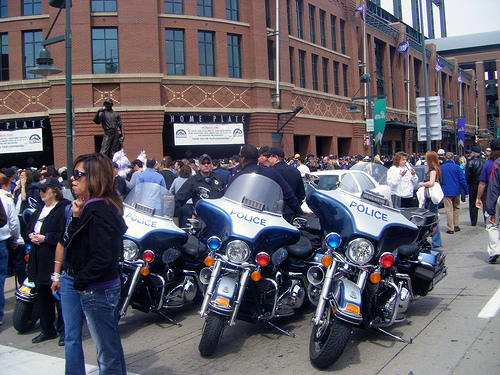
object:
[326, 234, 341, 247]
light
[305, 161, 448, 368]
motorcycle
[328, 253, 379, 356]
light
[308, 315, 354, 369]
tire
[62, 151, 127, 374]
woman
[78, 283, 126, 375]
jeans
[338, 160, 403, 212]
windshield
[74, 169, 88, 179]
glasses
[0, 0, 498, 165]
wall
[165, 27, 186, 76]
window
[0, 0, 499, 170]
building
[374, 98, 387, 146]
banner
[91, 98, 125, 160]
statue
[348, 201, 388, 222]
police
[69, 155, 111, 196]
head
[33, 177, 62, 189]
cap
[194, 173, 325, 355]
motorcycle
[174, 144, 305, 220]
police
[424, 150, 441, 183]
hair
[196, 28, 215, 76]
window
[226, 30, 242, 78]
window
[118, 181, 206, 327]
bikes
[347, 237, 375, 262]
headlight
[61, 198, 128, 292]
hoodie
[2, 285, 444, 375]
shadows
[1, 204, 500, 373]
ground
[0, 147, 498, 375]
crowd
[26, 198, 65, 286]
jacket